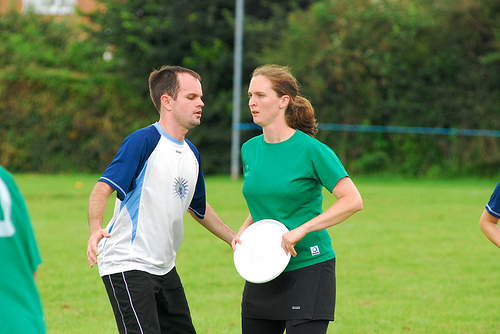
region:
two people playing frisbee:
[54, 18, 386, 328]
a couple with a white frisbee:
[82, 67, 367, 322]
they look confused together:
[74, 48, 360, 332]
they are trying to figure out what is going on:
[69, 43, 364, 330]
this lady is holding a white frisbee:
[219, 66, 368, 332]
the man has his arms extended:
[86, 39, 236, 319]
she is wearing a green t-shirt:
[227, 66, 369, 281]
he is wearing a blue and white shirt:
[54, 42, 214, 284]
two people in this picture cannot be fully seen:
[2, 79, 499, 330]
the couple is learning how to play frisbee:
[81, 54, 371, 331]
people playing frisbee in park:
[91, 65, 406, 316]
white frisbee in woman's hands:
[223, 230, 315, 290]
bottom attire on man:
[99, 258, 198, 326]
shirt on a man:
[94, 115, 206, 256]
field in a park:
[14, 171, 499, 318]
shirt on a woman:
[233, 133, 340, 250]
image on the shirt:
[164, 172, 190, 206]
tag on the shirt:
[306, 248, 325, 256]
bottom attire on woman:
[231, 260, 338, 329]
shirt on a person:
[2, 156, 72, 332]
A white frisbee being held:
[227, 226, 291, 278]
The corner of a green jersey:
[2, 158, 47, 332]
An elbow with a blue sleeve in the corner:
[482, 176, 499, 253]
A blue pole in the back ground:
[236, 113, 498, 143]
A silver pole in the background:
[230, 1, 240, 181]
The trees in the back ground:
[15, 13, 489, 170]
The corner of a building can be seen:
[3, 3, 135, 38]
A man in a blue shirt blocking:
[100, 72, 204, 332]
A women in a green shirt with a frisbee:
[215, 66, 365, 331]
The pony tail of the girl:
[282, 93, 319, 135]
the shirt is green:
[233, 128, 355, 277]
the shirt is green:
[216, 121, 368, 314]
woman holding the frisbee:
[205, 46, 397, 318]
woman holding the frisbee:
[184, 51, 360, 328]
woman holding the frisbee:
[191, 54, 348, 303]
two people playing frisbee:
[88, 67, 363, 332]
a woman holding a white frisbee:
[228, 216, 292, 281]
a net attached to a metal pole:
[229, 124, 499, 192]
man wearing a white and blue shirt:
[97, 121, 207, 276]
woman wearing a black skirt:
[241, 260, 337, 319]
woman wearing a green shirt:
[241, 129, 348, 269]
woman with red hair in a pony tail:
[247, 65, 317, 137]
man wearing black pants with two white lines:
[103, 268, 194, 333]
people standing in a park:
[6, 68, 499, 330]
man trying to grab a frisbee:
[86, 64, 232, 332]